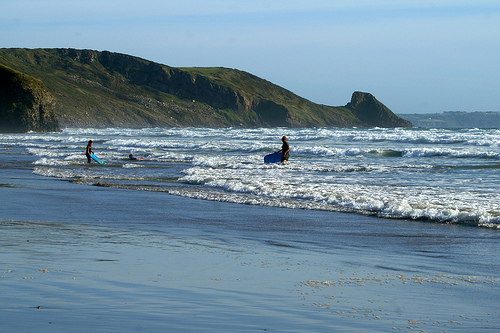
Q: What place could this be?
A: It is an ocean.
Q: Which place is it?
A: It is an ocean.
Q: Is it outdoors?
A: Yes, it is outdoors.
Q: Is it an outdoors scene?
A: Yes, it is outdoors.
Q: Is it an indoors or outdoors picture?
A: It is outdoors.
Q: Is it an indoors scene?
A: No, it is outdoors.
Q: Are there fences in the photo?
A: No, there are no fences.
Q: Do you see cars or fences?
A: No, there are no fences or cars.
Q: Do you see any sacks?
A: No, there are no sacks.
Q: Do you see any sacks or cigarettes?
A: No, there are no sacks or cigarettes.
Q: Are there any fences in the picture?
A: No, there are no fences.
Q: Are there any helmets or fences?
A: No, there are no fences or helmets.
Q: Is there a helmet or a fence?
A: No, there are no fences or helmets.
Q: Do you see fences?
A: No, there are no fences.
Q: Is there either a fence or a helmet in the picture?
A: No, there are no fences or helmets.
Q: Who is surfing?
A: The man is surfing.